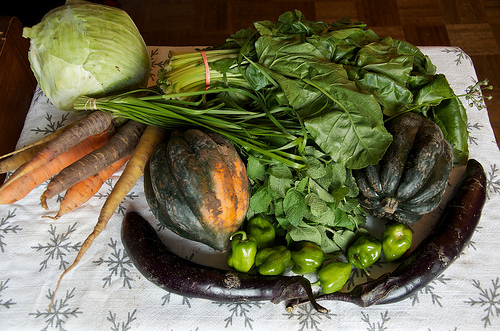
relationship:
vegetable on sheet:
[0, 0, 487, 309] [4, 30, 498, 327]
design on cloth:
[33, 218, 90, 329] [0, 45, 499, 330]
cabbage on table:
[24, 0, 150, 111] [18, 20, 497, 328]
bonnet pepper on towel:
[316, 261, 352, 294] [6, 35, 498, 329]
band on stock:
[83, 97, 96, 111] [69, 84, 311, 176]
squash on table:
[360, 105, 457, 225] [18, 20, 497, 328]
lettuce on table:
[283, 45, 405, 95] [18, 20, 497, 328]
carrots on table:
[2, 112, 162, 284] [18, 20, 497, 328]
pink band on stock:
[199, 51, 212, 90] [149, 39, 241, 106]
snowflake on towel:
[29, 219, 87, 273] [8, 212, 155, 322]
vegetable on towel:
[0, 0, 487, 309] [6, 35, 498, 329]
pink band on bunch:
[199, 51, 212, 90] [157, 11, 469, 166]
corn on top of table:
[140, 117, 257, 252] [2, 2, 492, 294]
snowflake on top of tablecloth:
[29, 219, 87, 273] [4, 34, 498, 324]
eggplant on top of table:
[123, 210, 305, 306] [18, 20, 497, 328]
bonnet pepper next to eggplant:
[227, 233, 254, 270] [342, 159, 494, 304]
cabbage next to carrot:
[8, 2, 150, 111] [2, 102, 119, 186]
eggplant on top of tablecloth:
[280, 153, 490, 315] [4, 34, 498, 324]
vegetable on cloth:
[13, 14, 481, 309] [0, 35, 500, 324]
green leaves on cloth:
[77, 7, 467, 169] [0, 35, 500, 324]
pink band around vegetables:
[192, 52, 216, 92] [168, 16, 438, 97]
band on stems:
[81, 93, 101, 113] [72, 86, 178, 128]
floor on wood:
[2, 1, 498, 109] [228, 9, 497, 79]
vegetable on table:
[0, 0, 487, 309] [18, 20, 497, 328]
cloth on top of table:
[0, 45, 499, 330] [18, 20, 497, 328]